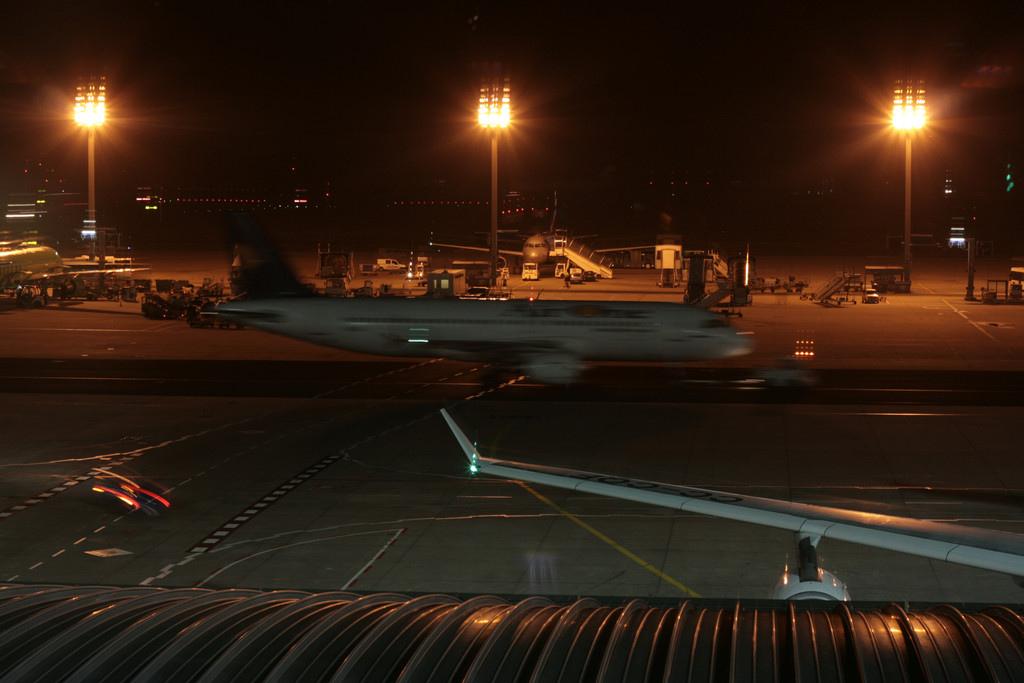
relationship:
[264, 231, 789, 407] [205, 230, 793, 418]
windows on an airplane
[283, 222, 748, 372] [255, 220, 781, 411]
windows on an airplane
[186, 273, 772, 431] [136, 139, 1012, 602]
plane sitting at airport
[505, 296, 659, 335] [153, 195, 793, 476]
name of plane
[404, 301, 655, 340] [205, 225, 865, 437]
windows on plane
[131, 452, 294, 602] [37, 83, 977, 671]
lines marking off of airport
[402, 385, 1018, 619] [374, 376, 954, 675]
wing on side of plane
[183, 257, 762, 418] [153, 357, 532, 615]
plane on concrete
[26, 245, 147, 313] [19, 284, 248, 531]
loading truck on runway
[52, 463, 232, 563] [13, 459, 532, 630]
stand stand on road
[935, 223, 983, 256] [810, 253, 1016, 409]
sign in back of road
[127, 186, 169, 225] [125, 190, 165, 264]
sign past pole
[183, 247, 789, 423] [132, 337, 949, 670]
airplane on runway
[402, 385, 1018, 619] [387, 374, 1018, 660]
wing on plane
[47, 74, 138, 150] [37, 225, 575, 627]
lights on runway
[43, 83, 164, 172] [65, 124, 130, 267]
pole connected to light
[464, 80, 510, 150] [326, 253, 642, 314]
light on runway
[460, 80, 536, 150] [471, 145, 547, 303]
pole to light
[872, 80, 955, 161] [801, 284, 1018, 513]
light on runway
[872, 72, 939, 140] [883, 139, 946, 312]
pole connected to light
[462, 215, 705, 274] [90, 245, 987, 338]
plane landed on ground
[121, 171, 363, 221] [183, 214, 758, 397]
buildings behind airplane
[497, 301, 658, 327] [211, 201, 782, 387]
writing on plane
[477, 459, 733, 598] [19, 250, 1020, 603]
line on ground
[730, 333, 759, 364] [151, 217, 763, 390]
nose on plane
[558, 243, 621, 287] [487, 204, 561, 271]
stairs leading to plane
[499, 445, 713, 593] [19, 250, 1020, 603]
stripe painted on ground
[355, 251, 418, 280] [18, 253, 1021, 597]
van parked on tarmac